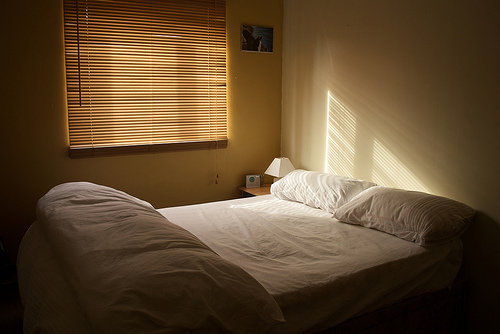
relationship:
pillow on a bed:
[321, 185, 492, 254] [22, 166, 473, 332]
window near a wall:
[63, 9, 238, 148] [8, 9, 58, 163]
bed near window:
[22, 166, 473, 332] [61, 0, 230, 159]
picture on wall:
[237, 23, 274, 54] [233, 60, 283, 147]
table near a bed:
[244, 171, 299, 198] [22, 166, 473, 332]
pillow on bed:
[331, 186, 478, 248] [22, 166, 473, 332]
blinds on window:
[62, 0, 227, 152] [61, 0, 230, 159]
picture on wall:
[239, 17, 273, 52] [238, 51, 339, 203]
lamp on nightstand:
[256, 144, 296, 194] [234, 164, 295, 195]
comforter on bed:
[12, 172, 284, 326] [22, 166, 473, 332]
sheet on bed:
[19, 192, 467, 334] [22, 166, 473, 332]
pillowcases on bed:
[277, 174, 353, 213] [22, 166, 473, 332]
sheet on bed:
[19, 192, 467, 334] [14, 160, 489, 326]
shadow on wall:
[277, 0, 500, 226] [288, 35, 451, 153]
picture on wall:
[237, 23, 274, 54] [228, 8, 284, 97]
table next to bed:
[236, 184, 272, 199] [22, 166, 473, 332]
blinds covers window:
[62, 0, 227, 152] [61, 0, 230, 159]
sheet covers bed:
[148, 187, 431, 305] [22, 166, 473, 332]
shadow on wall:
[311, 80, 455, 205] [287, 25, 490, 195]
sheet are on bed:
[19, 192, 467, 334] [22, 166, 473, 332]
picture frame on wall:
[237, 18, 276, 53] [231, 8, 280, 115]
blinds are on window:
[84, 16, 213, 115] [61, 0, 230, 159]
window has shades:
[61, 0, 230, 159] [181, 111, 217, 135]